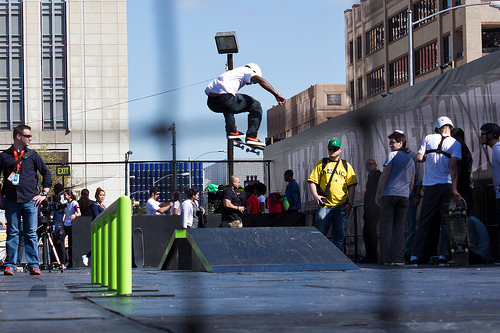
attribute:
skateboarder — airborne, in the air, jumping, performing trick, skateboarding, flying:
[204, 60, 287, 158]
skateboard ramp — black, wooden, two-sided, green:
[158, 226, 362, 273]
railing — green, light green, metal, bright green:
[88, 192, 135, 298]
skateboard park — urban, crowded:
[2, 55, 499, 332]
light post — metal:
[407, 1, 490, 90]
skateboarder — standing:
[402, 117, 472, 267]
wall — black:
[132, 212, 186, 269]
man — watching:
[308, 139, 360, 259]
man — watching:
[1, 122, 54, 278]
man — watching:
[373, 130, 417, 270]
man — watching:
[362, 156, 386, 264]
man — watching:
[477, 121, 499, 217]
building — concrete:
[343, 1, 499, 114]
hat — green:
[326, 136, 344, 151]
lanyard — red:
[12, 146, 27, 173]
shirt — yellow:
[307, 157, 362, 207]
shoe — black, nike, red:
[246, 134, 270, 151]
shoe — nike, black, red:
[226, 129, 250, 140]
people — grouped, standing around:
[209, 165, 303, 228]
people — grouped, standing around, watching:
[307, 113, 500, 269]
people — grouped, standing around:
[0, 120, 111, 277]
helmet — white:
[245, 61, 263, 78]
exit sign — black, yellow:
[55, 165, 72, 175]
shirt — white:
[204, 65, 257, 98]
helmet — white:
[432, 115, 454, 135]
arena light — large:
[213, 29, 241, 56]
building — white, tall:
[0, 1, 130, 207]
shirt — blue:
[2, 147, 54, 205]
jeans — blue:
[2, 199, 44, 270]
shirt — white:
[418, 132, 464, 188]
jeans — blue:
[206, 91, 264, 138]